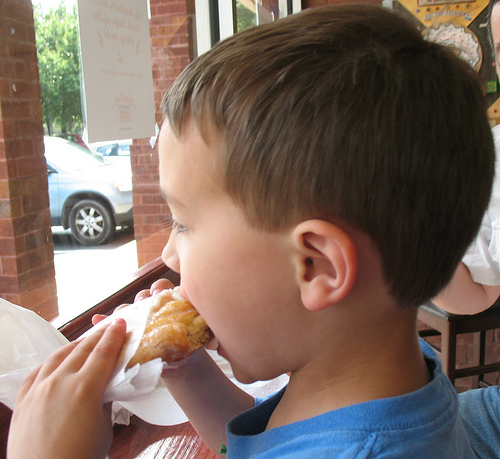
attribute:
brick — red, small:
[132, 203, 162, 214]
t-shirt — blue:
[251, 392, 448, 456]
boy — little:
[143, 112, 465, 424]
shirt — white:
[465, 117, 497, 284]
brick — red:
[9, 79, 34, 102]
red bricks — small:
[3, 105, 38, 177]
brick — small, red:
[0, 100, 30, 119]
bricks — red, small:
[0, 157, 57, 189]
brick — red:
[134, 165, 152, 199]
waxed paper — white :
[2, 286, 185, 413]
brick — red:
[12, 149, 47, 179]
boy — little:
[5, 7, 495, 457]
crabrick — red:
[128, 148, 152, 213]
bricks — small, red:
[10, 192, 44, 253]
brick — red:
[146, 2, 173, 23]